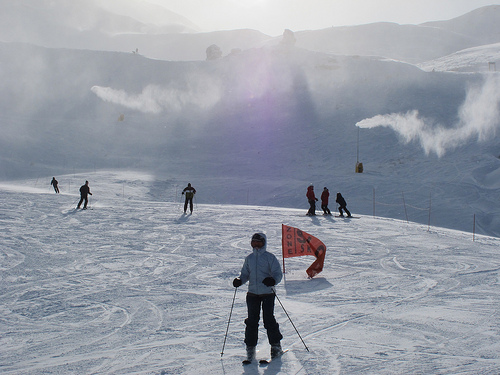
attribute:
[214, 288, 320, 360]
poles — black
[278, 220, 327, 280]
flag — orange, warning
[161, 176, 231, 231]
person — skiing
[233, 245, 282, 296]
parka — white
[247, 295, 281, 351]
pants — black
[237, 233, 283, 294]
jacket — light, blue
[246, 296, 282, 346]
pants — black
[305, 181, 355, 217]
skiers — three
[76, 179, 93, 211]
person — skiing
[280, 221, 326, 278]
flag — red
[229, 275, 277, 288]
gloves — black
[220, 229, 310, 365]
person — skiing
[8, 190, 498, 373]
slope — ski